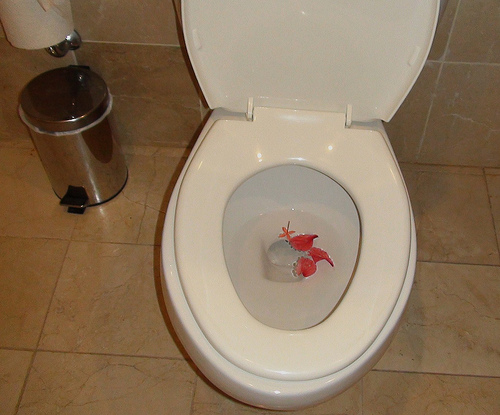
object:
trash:
[34, 78, 97, 118]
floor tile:
[35, 240, 190, 361]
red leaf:
[288, 231, 317, 253]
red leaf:
[291, 255, 317, 278]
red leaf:
[308, 246, 336, 268]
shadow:
[403, 280, 428, 362]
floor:
[0, 138, 499, 413]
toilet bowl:
[160, 110, 417, 395]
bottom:
[50, 165, 129, 208]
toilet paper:
[0, 0, 76, 51]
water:
[234, 209, 349, 323]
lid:
[178, 0, 440, 130]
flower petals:
[291, 254, 319, 278]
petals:
[285, 232, 318, 251]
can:
[16, 64, 129, 217]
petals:
[306, 246, 336, 268]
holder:
[43, 29, 83, 59]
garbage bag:
[18, 64, 110, 123]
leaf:
[277, 221, 297, 240]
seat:
[172, 107, 411, 381]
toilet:
[158, 0, 442, 412]